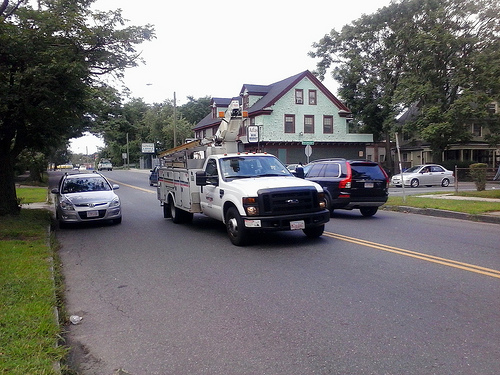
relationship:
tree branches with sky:
[63, 3, 162, 71] [122, 13, 252, 100]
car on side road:
[377, 153, 453, 196] [382, 172, 463, 209]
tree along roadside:
[7, 3, 87, 220] [13, 178, 238, 371]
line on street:
[321, 231, 499, 280] [55, 168, 499, 371]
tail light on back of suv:
[341, 175, 355, 190] [295, 156, 392, 220]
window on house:
[293, 87, 305, 107] [184, 71, 376, 165]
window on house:
[307, 88, 319, 108] [184, 71, 376, 165]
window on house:
[282, 111, 299, 136] [184, 71, 376, 165]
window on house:
[301, 114, 317, 134] [184, 71, 376, 165]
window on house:
[318, 113, 336, 136] [184, 71, 376, 165]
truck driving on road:
[148, 96, 335, 248] [51, 167, 499, 372]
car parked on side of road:
[53, 170, 124, 226] [51, 167, 499, 372]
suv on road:
[295, 156, 392, 220] [51, 167, 499, 372]